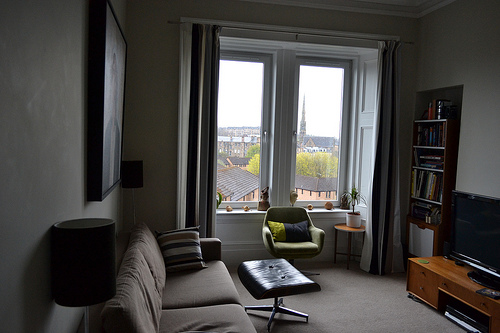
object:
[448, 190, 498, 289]
television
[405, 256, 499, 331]
entertainment consol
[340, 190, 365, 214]
plant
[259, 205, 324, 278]
chair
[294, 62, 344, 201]
window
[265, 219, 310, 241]
pillow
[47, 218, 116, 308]
lamp shade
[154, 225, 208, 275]
pillow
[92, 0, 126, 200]
painting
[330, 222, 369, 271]
table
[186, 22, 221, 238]
curtain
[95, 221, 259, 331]
sofa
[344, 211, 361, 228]
pot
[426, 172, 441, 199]
books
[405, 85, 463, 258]
bookcase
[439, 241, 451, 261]
speaker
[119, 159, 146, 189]
lamp shade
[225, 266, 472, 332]
floor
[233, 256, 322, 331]
seat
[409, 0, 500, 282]
wall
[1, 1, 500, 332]
living room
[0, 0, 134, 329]
wall